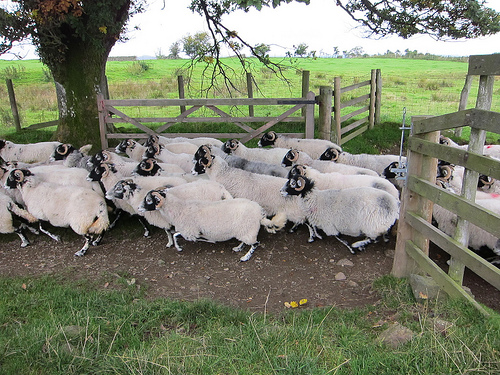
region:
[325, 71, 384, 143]
An opened wooden gate.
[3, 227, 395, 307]
Dirt trail the sheep run on.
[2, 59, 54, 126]
Green pasture to the left of a large tree.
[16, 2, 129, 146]
The largest green and brown tree trunk.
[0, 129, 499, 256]
Horned sheep running out a gate.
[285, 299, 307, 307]
Two yellow flowers in the dirt.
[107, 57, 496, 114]
Green field to the right of a large tree.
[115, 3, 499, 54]
White sky to the right of a tree.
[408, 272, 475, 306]
A large grey rock to the right of flowers in the dirt.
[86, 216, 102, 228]
yellow spot on the back of a white sheep's butt.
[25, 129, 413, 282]
herd of white sheep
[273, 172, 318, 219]
sheep have black faces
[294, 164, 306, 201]
sheep have tan horns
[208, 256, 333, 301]
brown dirt under sheep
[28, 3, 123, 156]
large tree near sheep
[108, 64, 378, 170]
brown and wooden fence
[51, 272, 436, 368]
green and tall grass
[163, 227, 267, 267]
sheep have white legs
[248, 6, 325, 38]
bright grey sky in distance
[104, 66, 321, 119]
brown posts by tree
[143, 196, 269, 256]
this is a sheep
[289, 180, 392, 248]
this is a sheep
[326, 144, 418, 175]
this is a sheep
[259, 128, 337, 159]
this is a sheep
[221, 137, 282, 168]
this is a sheep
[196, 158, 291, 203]
this is a sheep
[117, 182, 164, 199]
this is a sheep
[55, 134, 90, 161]
this is a sheep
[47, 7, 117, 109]
this is a tree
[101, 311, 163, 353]
the grass is short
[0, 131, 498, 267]
rams are running away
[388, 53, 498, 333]
fence made of wood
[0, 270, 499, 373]
some grass on the ground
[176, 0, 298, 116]
branches are hanging down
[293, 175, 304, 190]
horn of a ram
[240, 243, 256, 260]
leg of a ram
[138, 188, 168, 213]
head of a ram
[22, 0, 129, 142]
a thick tree trunk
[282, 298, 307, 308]
flowers on the ground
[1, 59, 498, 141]
grass is bright green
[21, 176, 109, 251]
white ram on dirt path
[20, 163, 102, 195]
white ram on dirt path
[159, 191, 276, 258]
white ram on dirt path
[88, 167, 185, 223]
white ram on dirt path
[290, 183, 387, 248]
white ram on dirt path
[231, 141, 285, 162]
white ram on dirt path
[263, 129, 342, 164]
white ram on dirt path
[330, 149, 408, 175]
white ram on dirt path